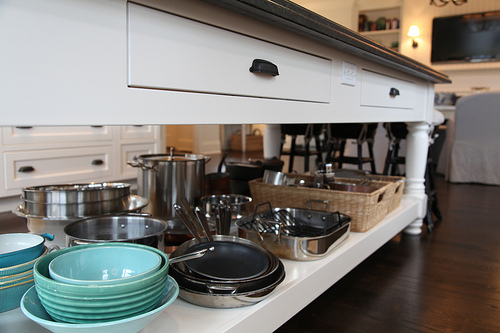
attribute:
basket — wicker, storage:
[247, 177, 395, 234]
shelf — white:
[54, 93, 409, 304]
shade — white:
[409, 25, 422, 37]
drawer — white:
[128, 4, 341, 105]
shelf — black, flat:
[428, 62, 491, 78]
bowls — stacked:
[22, 233, 196, 321]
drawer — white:
[8, 125, 130, 195]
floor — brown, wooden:
[286, 171, 496, 331]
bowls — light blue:
[32, 237, 189, 304]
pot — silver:
[68, 189, 186, 249]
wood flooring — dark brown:
[415, 255, 482, 315]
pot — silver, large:
[133, 140, 208, 238]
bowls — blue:
[22, 240, 182, 330]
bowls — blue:
[0, 226, 49, 311]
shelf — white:
[133, 195, 432, 330]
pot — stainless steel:
[121, 147, 213, 199]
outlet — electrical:
[339, 60, 358, 89]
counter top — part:
[0, 1, 453, 123]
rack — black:
[239, 200, 342, 235]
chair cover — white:
[442, 87, 498, 181]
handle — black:
[248, 57, 280, 75]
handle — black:
[388, 87, 401, 98]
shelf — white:
[1, 193, 426, 332]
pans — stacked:
[171, 210, 286, 304]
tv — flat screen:
[427, 7, 497, 69]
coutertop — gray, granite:
[300, 0, 448, 80]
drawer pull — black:
[246, 57, 283, 79]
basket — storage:
[249, 169, 408, 231]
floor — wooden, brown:
[268, 180, 498, 331]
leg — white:
[405, 120, 431, 235]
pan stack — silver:
[169, 226, 286, 306]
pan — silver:
[247, 193, 352, 253]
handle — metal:
[191, 204, 215, 247]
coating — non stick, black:
[191, 243, 262, 276]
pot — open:
[63, 212, 175, 249]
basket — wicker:
[306, 169, 406, 211]